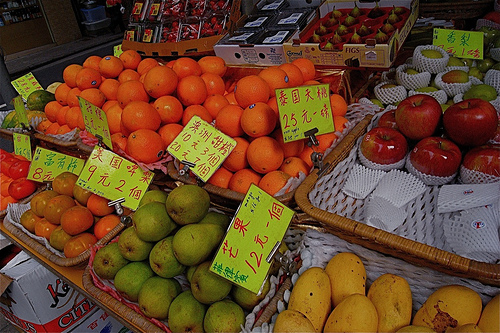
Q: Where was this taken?
A: Market.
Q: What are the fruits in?
A: Baskets.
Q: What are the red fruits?
A: Apples.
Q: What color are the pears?
A: Green.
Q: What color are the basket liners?
A: White.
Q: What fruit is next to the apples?
A: Oranges.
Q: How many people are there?
A: 0.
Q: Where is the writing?
A: On the yellow signs.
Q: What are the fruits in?
A: Baskets.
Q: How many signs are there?
A: 10.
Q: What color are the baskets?
A: Brown.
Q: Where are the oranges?
A: Next to the apples.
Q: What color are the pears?
A: Green.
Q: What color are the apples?
A: Red.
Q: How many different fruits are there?
A: 7.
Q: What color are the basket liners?
A: White.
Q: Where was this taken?
A: Market.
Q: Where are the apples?
A: Next to the oranges.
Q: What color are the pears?
A: Green.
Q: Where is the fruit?
A: In baskets.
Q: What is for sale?
A: Fruit.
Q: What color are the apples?
A: Red.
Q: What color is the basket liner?
A: White.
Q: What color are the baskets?
A: Brown.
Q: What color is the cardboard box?
A: Orange and white.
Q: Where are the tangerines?
A: Next to the pears.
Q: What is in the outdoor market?
A: Fruit stand.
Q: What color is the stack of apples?
A: Red.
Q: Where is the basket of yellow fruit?
A: On the stand.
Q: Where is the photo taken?
A: At a fruit stand.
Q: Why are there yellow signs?
A: To advertise the price of the fruit.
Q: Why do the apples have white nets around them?
A: To protect them from bruising.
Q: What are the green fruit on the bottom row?
A: Pears.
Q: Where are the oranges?
A: On the top row.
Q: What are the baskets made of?
A: Wicker.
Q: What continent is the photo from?
A: Asia.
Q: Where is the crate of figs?
A: In the back.